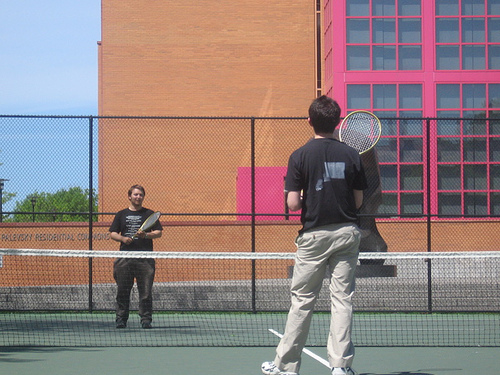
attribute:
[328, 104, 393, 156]
racket — silver tennis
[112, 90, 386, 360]
players — two tennis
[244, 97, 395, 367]
boy — playing tennis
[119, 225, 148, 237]
hands — both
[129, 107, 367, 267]
racket — white and yellow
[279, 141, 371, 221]
shirt — black, short sleeves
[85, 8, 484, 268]
building — Letters, background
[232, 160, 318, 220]
building — Red box 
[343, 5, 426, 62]
window — clear and clean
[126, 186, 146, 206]
face — white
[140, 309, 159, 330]
shoe — laced and white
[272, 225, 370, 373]
pants — tan and long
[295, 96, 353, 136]
man — head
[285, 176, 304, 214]
man — arm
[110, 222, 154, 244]
man — hand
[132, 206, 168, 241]
racket — tennis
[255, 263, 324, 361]
man — leg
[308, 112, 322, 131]
man — ear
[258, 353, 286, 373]
shoe — white tennis 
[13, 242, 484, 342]
net — white, black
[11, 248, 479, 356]
fence —  large chain link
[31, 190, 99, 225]
tree — green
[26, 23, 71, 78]
sky — blue.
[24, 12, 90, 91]
sky — clear.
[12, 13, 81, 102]
trees — background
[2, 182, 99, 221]
trees — green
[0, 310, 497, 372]
ground — green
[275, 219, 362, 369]
pants — white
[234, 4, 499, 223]
building — red